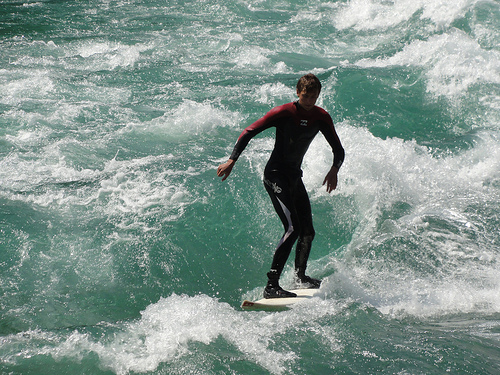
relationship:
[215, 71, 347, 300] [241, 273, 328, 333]
man riding surfboard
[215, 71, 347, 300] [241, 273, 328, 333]
man on surfboard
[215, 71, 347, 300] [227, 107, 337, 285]
man wearing wetsuit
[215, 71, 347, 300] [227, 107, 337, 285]
man in wetsuit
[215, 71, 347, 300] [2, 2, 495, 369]
man facing water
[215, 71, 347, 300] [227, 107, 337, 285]
man red black and gray wetsuit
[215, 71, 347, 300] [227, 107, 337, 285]
man wearing red wetsuit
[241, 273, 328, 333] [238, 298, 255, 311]
surfboard with a red tip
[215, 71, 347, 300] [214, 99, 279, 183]
man extending arm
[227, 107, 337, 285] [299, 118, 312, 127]
wetsuit has logo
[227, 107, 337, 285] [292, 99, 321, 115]
wetsuit has black neck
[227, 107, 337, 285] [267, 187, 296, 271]
wetsuit has white stripe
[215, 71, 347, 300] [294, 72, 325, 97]
man has hair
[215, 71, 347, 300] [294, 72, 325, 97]
man has short hair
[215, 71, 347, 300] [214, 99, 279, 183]
man bending arm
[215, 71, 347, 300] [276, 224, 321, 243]
man bending knees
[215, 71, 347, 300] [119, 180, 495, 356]
man riding wave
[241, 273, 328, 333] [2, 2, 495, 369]
surfboard on water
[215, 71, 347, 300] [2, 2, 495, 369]
man in water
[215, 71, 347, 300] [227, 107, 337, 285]
man wearing a wetsuit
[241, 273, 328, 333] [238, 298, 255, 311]
surfboard has pointy tip